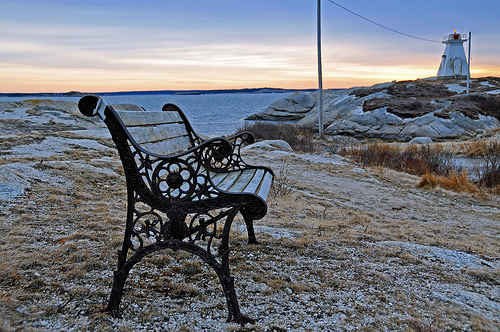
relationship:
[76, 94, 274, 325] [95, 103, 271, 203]
bench has ice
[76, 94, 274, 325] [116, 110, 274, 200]
bench has wood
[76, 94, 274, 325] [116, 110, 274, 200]
bench made up of wood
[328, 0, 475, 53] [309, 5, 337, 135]
wire on pole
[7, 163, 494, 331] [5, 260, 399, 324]
ground has gravel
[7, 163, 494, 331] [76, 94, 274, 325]
grounud has bench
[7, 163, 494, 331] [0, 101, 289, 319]
ground has rocks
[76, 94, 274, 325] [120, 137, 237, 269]
bench has design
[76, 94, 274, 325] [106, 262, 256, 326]
bench has leg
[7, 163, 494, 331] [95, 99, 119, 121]
ground has snow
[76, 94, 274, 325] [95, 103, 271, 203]
bench has frost